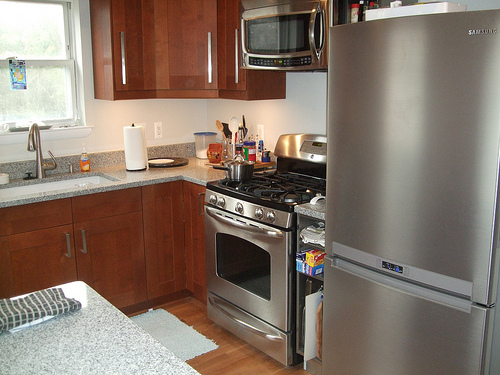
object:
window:
[215, 232, 271, 302]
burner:
[203, 172, 326, 228]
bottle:
[80, 152, 90, 172]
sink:
[0, 173, 119, 200]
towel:
[0, 288, 81, 335]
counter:
[101, 156, 227, 187]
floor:
[127, 298, 308, 374]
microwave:
[240, 4, 329, 72]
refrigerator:
[322, 9, 499, 375]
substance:
[196, 150, 207, 158]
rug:
[129, 308, 218, 364]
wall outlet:
[154, 123, 162, 139]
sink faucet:
[27, 123, 57, 180]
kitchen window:
[0, 1, 76, 128]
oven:
[205, 203, 292, 367]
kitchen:
[0, 1, 499, 375]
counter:
[0, 280, 200, 374]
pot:
[209, 155, 254, 181]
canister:
[194, 131, 216, 158]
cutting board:
[302, 292, 320, 360]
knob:
[209, 195, 217, 204]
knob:
[217, 197, 226, 207]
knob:
[234, 201, 243, 212]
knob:
[254, 207, 264, 219]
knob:
[265, 210, 275, 224]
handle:
[208, 297, 286, 344]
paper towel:
[123, 126, 148, 170]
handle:
[64, 233, 72, 257]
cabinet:
[1, 181, 207, 314]